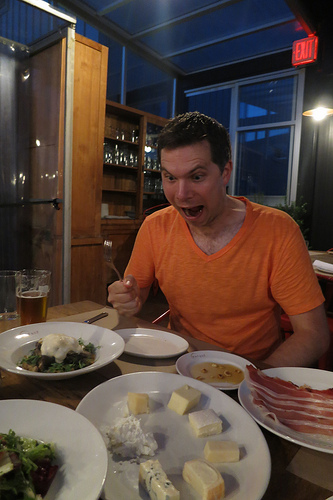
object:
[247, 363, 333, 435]
bacon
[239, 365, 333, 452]
plate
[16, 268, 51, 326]
glass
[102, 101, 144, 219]
cabinet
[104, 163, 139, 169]
shelf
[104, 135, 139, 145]
shelf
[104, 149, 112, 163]
glass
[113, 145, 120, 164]
glass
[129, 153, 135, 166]
glass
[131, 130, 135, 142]
glass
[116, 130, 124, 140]
glass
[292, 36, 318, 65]
exit sign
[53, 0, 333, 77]
ceiling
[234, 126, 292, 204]
window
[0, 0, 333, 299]
building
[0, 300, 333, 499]
table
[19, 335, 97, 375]
salad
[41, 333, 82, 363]
dressing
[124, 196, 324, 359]
shirt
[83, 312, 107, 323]
utensil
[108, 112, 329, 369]
man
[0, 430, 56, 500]
salad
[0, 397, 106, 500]
bowl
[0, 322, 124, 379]
plates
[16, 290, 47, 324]
beer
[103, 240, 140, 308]
fork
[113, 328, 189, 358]
plate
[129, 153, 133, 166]
glassware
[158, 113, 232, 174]
hair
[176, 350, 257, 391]
plate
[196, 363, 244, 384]
sauce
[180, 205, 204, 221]
mouth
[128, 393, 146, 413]
cheese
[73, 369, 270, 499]
plate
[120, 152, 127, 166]
glasses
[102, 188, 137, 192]
shelves